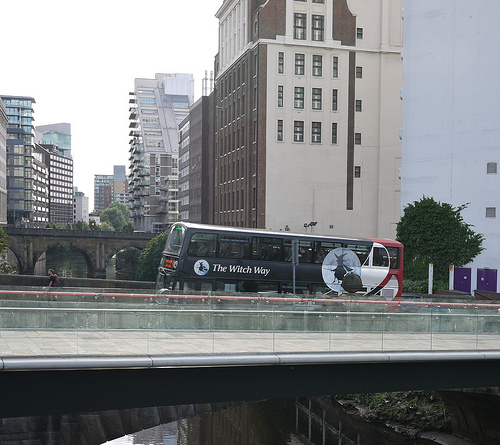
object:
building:
[397, 0, 499, 297]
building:
[189, 70, 214, 225]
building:
[178, 110, 192, 222]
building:
[128, 72, 196, 233]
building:
[0, 94, 51, 229]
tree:
[394, 193, 486, 296]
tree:
[134, 229, 173, 282]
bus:
[151, 221, 404, 318]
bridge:
[0, 283, 496, 420]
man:
[46, 269, 60, 301]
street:
[0, 290, 499, 331]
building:
[35, 123, 80, 228]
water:
[192, 406, 331, 445]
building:
[213, 0, 402, 241]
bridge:
[0, 227, 160, 280]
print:
[213, 263, 271, 277]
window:
[295, 53, 305, 75]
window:
[293, 120, 303, 142]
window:
[312, 121, 322, 143]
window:
[332, 123, 338, 145]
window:
[355, 166, 361, 178]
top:
[159, 219, 403, 271]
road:
[0, 330, 499, 357]